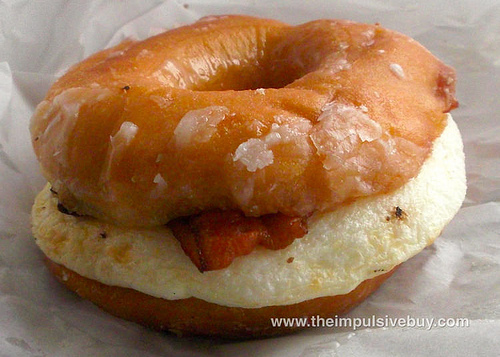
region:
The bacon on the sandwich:
[168, 174, 301, 274]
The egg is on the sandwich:
[276, 200, 423, 290]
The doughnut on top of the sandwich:
[128, 97, 389, 182]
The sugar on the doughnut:
[173, 108, 283, 183]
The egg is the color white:
[315, 177, 453, 268]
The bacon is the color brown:
[180, 215, 292, 257]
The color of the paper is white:
[424, 241, 489, 355]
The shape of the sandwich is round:
[35, 61, 461, 346]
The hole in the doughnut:
[156, 30, 338, 105]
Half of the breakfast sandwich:
[246, 10, 473, 346]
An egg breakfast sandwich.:
[29, 10, 471, 337]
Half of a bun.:
[27, 10, 447, 227]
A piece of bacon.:
[165, 201, 308, 273]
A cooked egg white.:
[29, 114, 471, 309]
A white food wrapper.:
[0, 3, 499, 353]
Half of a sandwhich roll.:
[49, 260, 409, 340]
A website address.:
[270, 311, 472, 329]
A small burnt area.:
[389, 204, 408, 223]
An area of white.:
[173, 99, 227, 150]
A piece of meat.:
[51, 200, 86, 216]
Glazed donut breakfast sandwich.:
[16, 12, 483, 354]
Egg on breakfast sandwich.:
[31, 114, 473, 310]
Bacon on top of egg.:
[158, 209, 312, 272]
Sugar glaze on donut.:
[40, 86, 390, 208]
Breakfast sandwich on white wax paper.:
[10, 1, 447, 350]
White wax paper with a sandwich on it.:
[1, 2, 493, 353]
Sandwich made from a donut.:
[21, 12, 466, 344]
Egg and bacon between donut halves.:
[27, 4, 471, 341]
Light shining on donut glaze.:
[110, 52, 245, 89]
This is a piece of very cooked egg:
[407, 182, 435, 259]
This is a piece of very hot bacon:
[224, 224, 255, 284]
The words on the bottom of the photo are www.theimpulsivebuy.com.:
[316, 306, 469, 318]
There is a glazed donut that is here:
[247, 108, 278, 168]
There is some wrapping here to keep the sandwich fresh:
[468, 265, 487, 340]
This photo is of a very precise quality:
[126, 23, 332, 355]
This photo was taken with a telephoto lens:
[156, 30, 361, 327]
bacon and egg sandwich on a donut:
[27, 8, 488, 333]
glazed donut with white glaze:
[57, 18, 445, 181]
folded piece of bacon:
[178, 204, 310, 268]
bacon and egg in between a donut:
[85, 175, 458, 288]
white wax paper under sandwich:
[10, 0, 480, 352]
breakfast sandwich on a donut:
[37, 22, 473, 336]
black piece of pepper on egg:
[382, 198, 419, 231]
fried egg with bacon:
[41, 165, 487, 301]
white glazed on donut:
[175, 99, 229, 149]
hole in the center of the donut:
[147, 35, 330, 120]